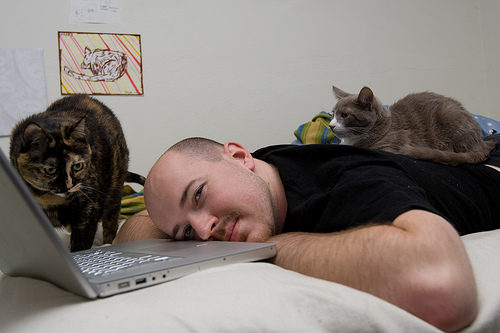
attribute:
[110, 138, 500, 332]
man — laying, resting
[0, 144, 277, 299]
laptop — silver, open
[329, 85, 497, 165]
cat — laying, gray, furry, white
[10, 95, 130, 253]
cat — standing, calico, furry, looking, dark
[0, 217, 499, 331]
comforter — white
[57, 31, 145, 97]
picture — colorful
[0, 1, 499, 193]
wall — white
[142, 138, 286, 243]
head — bald, shaved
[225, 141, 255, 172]
ear — pink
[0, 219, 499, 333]
bed — white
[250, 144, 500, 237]
shirt — black